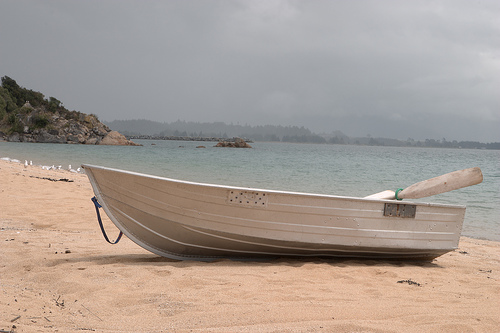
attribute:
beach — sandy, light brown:
[1, 159, 499, 331]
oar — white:
[377, 149, 477, 206]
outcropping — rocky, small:
[215, 136, 252, 146]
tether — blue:
[88, 191, 125, 252]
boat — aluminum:
[77, 161, 465, 265]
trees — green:
[0, 76, 57, 102]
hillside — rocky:
[0, 77, 137, 145]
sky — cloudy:
[2, 1, 485, 163]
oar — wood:
[367, 161, 490, 206]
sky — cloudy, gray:
[169, 21, 469, 135]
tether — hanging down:
[91, 186, 126, 238]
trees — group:
[6, 61, 92, 141]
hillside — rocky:
[13, 80, 132, 138]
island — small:
[262, 135, 396, 196]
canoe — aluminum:
[84, 135, 483, 281]